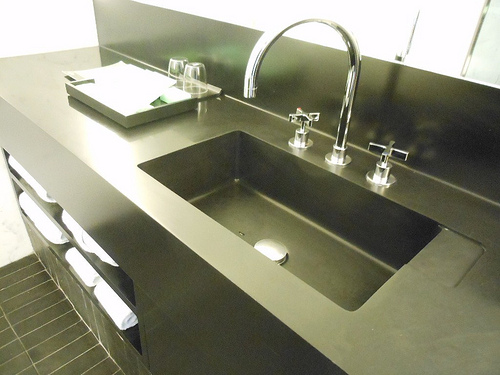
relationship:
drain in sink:
[257, 214, 302, 268] [85, 57, 457, 326]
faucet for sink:
[233, 2, 373, 159] [85, 57, 457, 326]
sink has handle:
[85, 57, 457, 326] [271, 100, 344, 152]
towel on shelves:
[13, 190, 58, 256] [10, 141, 158, 351]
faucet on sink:
[233, 2, 373, 159] [85, 57, 457, 326]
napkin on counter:
[92, 58, 180, 105] [406, 257, 499, 333]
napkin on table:
[122, 58, 174, 95] [38, 27, 205, 170]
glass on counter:
[160, 44, 245, 116] [2, 46, 497, 373]